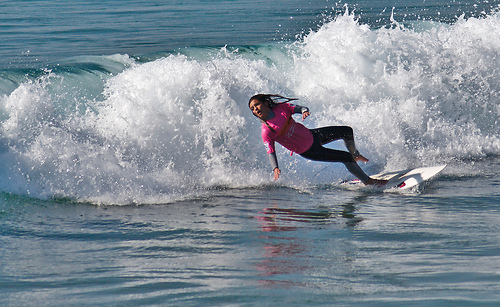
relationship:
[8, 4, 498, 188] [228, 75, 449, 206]
wave behind surfer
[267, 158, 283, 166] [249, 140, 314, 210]
band on arm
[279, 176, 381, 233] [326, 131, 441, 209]
shadow on surfboard